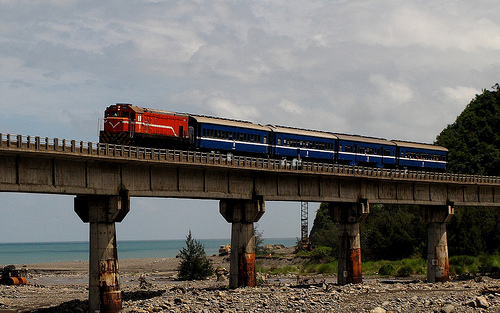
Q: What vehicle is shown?
A: A train.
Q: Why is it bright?
A: It is sunny.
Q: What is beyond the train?
A: The ocean.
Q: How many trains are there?
A: One.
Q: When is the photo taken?
A: Daytime.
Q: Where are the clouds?
A: In the sky.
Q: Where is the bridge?
A: Over the beach.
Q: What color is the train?
A: Red and blue.